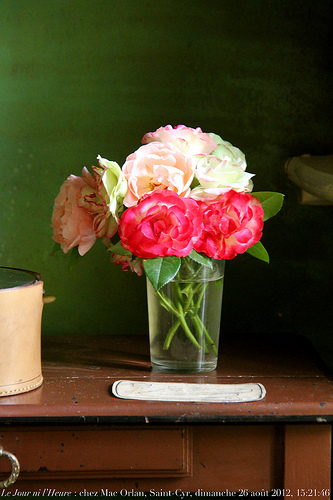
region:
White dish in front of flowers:
[105, 379, 271, 401]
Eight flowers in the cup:
[50, 123, 265, 259]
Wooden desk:
[0, 262, 53, 396]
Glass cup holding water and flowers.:
[143, 251, 223, 372]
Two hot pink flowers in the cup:
[117, 188, 262, 260]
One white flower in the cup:
[192, 152, 257, 195]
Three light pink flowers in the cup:
[51, 122, 215, 255]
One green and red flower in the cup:
[78, 151, 125, 239]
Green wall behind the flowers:
[1, 98, 327, 339]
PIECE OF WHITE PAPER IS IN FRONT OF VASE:
[112, 379, 279, 411]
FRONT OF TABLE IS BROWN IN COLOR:
[5, 421, 325, 494]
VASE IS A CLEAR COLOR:
[145, 252, 219, 370]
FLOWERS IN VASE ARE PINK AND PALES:
[49, 121, 279, 277]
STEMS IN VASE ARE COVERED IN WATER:
[141, 270, 245, 370]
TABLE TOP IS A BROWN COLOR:
[31, 324, 329, 409]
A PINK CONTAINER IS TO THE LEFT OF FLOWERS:
[0, 264, 56, 389]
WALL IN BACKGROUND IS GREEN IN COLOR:
[14, 22, 308, 114]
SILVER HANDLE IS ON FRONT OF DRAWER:
[0, 445, 20, 489]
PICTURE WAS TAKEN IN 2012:
[268, 488, 294, 498]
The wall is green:
[1, 2, 312, 273]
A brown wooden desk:
[4, 319, 319, 479]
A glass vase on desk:
[130, 243, 233, 378]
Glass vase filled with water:
[130, 253, 251, 375]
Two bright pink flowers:
[106, 175, 273, 272]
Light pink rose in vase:
[46, 161, 103, 256]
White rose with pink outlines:
[137, 117, 219, 174]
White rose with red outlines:
[71, 149, 132, 246]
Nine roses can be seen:
[43, 108, 279, 273]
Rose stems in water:
[136, 266, 224, 364]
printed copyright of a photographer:
[3, 480, 332, 498]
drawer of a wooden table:
[5, 423, 214, 484]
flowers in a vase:
[52, 100, 290, 269]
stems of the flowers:
[153, 280, 211, 359]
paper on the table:
[106, 365, 272, 406]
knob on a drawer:
[1, 444, 23, 492]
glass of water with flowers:
[138, 257, 237, 374]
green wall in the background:
[21, 19, 323, 129]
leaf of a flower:
[259, 184, 292, 219]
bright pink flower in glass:
[112, 187, 207, 264]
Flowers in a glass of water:
[48, 122, 292, 375]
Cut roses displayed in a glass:
[48, 122, 288, 373]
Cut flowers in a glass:
[48, 121, 293, 375]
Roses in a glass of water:
[49, 123, 285, 373]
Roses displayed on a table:
[50, 123, 290, 384]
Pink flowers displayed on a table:
[49, 123, 287, 382]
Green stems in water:
[50, 108, 285, 375]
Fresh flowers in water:
[48, 120, 290, 374]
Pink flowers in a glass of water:
[50, 122, 281, 376]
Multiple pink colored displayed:
[48, 120, 288, 373]